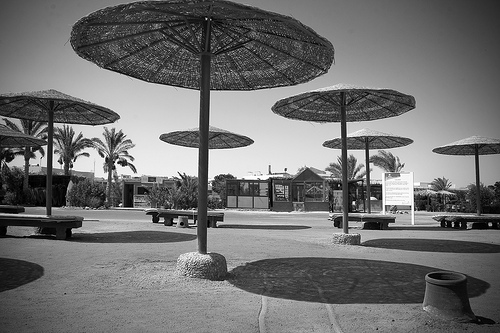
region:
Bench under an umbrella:
[1, 74, 119, 245]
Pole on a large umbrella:
[195, 31, 219, 253]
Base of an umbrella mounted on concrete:
[174, 243, 234, 284]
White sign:
[376, 157, 426, 227]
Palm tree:
[85, 128, 137, 208]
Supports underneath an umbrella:
[160, 18, 251, 57]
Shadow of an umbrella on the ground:
[232, 246, 432, 316]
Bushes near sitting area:
[143, 165, 220, 218]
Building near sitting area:
[239, 159, 345, 211]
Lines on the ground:
[252, 283, 347, 331]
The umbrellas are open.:
[34, 4, 425, 159]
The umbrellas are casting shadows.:
[230, 227, 455, 332]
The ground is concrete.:
[120, 258, 190, 331]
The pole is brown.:
[188, 26, 222, 251]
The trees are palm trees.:
[48, 126, 153, 215]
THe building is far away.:
[216, 162, 399, 232]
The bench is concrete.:
[11, 194, 80, 261]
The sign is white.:
[370, 149, 411, 231]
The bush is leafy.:
[143, 182, 243, 214]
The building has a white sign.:
[232, 182, 344, 239]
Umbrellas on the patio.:
[65, 16, 458, 323]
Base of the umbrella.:
[178, 232, 265, 327]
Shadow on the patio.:
[209, 246, 460, 324]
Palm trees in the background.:
[44, 112, 168, 223]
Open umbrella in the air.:
[158, 98, 328, 170]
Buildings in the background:
[28, 135, 286, 227]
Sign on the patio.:
[365, 155, 458, 250]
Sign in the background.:
[378, 165, 420, 219]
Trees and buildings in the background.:
[114, 155, 295, 246]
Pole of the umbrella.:
[168, 38, 246, 331]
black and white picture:
[23, 38, 481, 295]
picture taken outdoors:
[32, 15, 479, 315]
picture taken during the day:
[10, 130, 484, 328]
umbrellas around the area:
[40, 27, 445, 273]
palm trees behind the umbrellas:
[41, 91, 299, 186]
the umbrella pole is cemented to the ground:
[140, 90, 268, 315]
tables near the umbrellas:
[136, 182, 492, 228]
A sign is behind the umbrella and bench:
[346, 131, 452, 226]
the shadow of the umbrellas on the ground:
[236, 230, 477, 325]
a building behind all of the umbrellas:
[217, 155, 427, 255]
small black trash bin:
[408, 259, 479, 324]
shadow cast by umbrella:
[218, 236, 495, 322]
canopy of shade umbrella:
[64, 2, 341, 97]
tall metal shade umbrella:
[64, 2, 337, 289]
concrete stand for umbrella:
[168, 245, 237, 290]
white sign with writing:
[373, 163, 423, 231]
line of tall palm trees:
[3, 107, 145, 219]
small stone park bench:
[323, 196, 400, 238]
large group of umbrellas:
[2, 0, 497, 330]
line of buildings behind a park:
[1, 151, 492, 228]